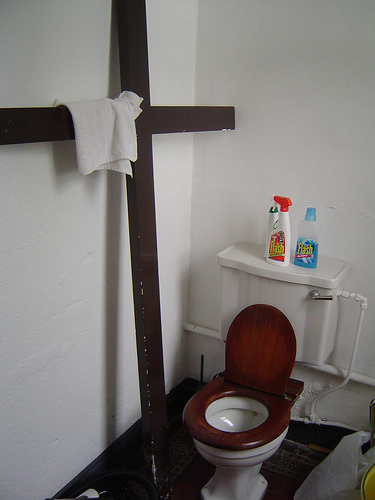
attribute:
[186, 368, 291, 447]
seat — brown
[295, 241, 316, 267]
liquid — blue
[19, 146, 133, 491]
wall — white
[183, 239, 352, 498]
toilet — white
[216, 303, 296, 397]
lid — up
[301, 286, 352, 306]
handle — silver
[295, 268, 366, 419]
pipe — white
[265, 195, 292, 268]
bottle — orange, white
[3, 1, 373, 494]
walls — white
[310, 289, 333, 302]
handle — metal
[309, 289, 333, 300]
handle — metallic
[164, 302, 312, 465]
toilet — wooden